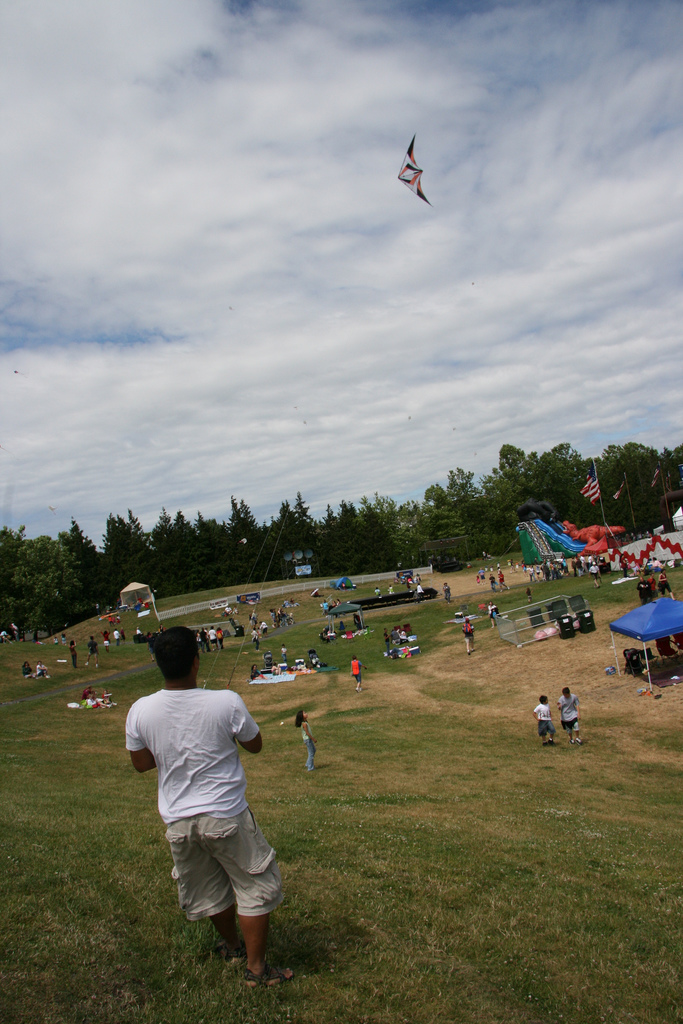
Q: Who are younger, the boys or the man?
A: The boys are younger than the man.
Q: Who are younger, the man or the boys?
A: The boys are younger than the man.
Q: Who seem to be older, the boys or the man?
A: The man are older than the boys.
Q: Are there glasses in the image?
A: No, there are no glasses.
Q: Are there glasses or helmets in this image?
A: No, there are no glasses or helmets.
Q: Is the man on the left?
A: Yes, the man is on the left of the image.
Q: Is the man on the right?
A: No, the man is on the left of the image.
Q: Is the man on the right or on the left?
A: The man is on the left of the image.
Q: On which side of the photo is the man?
A: The man is on the left of the image.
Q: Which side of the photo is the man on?
A: The man is on the left of the image.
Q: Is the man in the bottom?
A: Yes, the man is in the bottom of the image.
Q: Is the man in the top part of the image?
A: No, the man is in the bottom of the image.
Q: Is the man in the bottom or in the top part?
A: The man is in the bottom of the image.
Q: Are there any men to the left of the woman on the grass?
A: Yes, there is a man to the left of the woman.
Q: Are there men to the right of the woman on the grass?
A: No, the man is to the left of the woman.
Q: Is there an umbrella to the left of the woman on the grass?
A: No, there is a man to the left of the woman.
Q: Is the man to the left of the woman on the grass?
A: Yes, the man is to the left of the woman.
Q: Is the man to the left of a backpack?
A: No, the man is to the left of the woman.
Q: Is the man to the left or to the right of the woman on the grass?
A: The man is to the left of the woman.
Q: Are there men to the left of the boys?
A: Yes, there is a man to the left of the boys.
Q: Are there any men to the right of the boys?
A: No, the man is to the left of the boys.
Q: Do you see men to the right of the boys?
A: No, the man is to the left of the boys.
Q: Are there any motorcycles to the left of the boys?
A: No, there is a man to the left of the boys.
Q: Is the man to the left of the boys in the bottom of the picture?
A: Yes, the man is to the left of the boys.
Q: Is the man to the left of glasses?
A: No, the man is to the left of the boys.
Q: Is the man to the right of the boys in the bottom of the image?
A: No, the man is to the left of the boys.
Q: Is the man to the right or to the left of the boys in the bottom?
A: The man is to the left of the boys.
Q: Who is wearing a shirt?
A: The man is wearing a shirt.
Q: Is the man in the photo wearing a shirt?
A: Yes, the man is wearing a shirt.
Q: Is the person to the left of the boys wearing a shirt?
A: Yes, the man is wearing a shirt.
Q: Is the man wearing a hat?
A: No, the man is wearing a shirt.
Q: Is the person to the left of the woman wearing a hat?
A: No, the man is wearing a shirt.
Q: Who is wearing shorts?
A: The man is wearing shorts.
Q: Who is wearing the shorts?
A: The man is wearing shorts.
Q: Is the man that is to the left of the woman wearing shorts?
A: Yes, the man is wearing shorts.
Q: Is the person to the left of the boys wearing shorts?
A: Yes, the man is wearing shorts.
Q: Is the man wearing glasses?
A: No, the man is wearing shorts.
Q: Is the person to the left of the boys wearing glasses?
A: No, the man is wearing shorts.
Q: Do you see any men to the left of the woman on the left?
A: Yes, there is a man to the left of the woman.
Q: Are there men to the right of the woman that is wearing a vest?
A: No, the man is to the left of the woman.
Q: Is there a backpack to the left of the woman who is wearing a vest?
A: No, there is a man to the left of the woman.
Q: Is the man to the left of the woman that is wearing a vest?
A: Yes, the man is to the left of the woman.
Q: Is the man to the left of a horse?
A: No, the man is to the left of the woman.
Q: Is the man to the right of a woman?
A: No, the man is to the left of a woman.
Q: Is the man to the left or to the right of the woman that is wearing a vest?
A: The man is to the left of the woman.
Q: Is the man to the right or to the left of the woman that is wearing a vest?
A: The man is to the left of the woman.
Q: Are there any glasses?
A: No, there are no glasses.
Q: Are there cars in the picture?
A: No, there are no cars.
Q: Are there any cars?
A: No, there are no cars.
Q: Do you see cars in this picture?
A: No, there are no cars.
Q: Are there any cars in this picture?
A: No, there are no cars.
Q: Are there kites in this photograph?
A: Yes, there is a kite.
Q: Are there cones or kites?
A: Yes, there is a kite.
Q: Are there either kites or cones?
A: Yes, there is a kite.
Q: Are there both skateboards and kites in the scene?
A: No, there is a kite but no skateboards.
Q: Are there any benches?
A: No, there are no benches.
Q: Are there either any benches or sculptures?
A: No, there are no benches or sculptures.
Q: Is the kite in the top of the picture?
A: Yes, the kite is in the top of the image.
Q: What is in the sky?
A: The kite is in the sky.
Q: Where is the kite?
A: The kite is in the sky.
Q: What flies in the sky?
A: The kite flies in the sky.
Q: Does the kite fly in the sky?
A: Yes, the kite flies in the sky.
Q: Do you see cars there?
A: No, there are no cars.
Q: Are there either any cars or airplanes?
A: No, there are no cars or airplanes.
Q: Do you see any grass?
A: Yes, there is grass.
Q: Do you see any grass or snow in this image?
A: Yes, there is grass.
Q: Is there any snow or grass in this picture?
A: Yes, there is grass.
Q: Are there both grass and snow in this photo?
A: No, there is grass but no snow.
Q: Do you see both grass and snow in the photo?
A: No, there is grass but no snow.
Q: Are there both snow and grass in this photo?
A: No, there is grass but no snow.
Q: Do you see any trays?
A: No, there are no trays.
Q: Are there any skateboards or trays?
A: No, there are no trays or skateboards.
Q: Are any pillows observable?
A: No, there are no pillows.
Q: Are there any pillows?
A: No, there are no pillows.